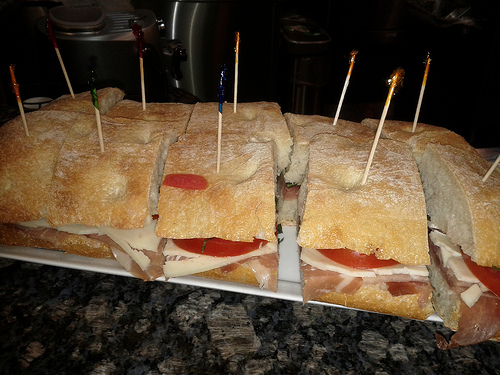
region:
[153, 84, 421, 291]
the toothpick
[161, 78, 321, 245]
the toothpick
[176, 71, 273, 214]
the toothpick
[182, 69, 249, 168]
the toothpick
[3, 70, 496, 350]
a sub sandwich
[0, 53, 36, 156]
Orange toothpick in sandwich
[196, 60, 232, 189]
blue toothpick in sandwich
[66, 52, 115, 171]
green toothpick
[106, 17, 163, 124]
red toothpick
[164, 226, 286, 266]
tomato in sandwich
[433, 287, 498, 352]
mean inside of sandwich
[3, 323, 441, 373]
Grey counter top.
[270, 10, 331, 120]
Side table in the background.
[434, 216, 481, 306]
White cheese inside of sub sandwich.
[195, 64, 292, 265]
The tooth pick is in the food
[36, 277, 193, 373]
The counter is dark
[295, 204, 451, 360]
The sandwich has tomatoes on it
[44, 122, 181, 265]
The bread is brown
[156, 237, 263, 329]
The sandwich has cheese on i t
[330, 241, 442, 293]
The tomatoes are red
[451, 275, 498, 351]
The sandwich has meat on it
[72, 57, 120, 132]
The top of the tooth pick is green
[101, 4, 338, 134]
The background is dark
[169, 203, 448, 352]
The sandwich is cut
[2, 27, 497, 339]
a large sandwich cut into smaller sandwiches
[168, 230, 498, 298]
pieces of tomato in the sandwhich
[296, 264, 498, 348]
bacon on the sandwhich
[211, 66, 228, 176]
a blue toothpick in the sandwhich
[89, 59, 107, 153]
a green toothpick in the sandwhich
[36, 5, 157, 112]
two red toothpicks in the sandwhich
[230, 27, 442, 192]
four orange toothpicks in the sandwhich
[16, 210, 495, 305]
cheese on the sandwhich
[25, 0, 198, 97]
a drink dispenser in the background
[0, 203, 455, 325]
white serving plate holding sandwhich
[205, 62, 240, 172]
toothpick with blue cellophane wrap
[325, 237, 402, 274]
tomato slice in sandwich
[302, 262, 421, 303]
prosciutto in sandwich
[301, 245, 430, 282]
slice of mozzarella cheese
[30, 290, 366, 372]
black marble counter top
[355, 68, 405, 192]
toothpick with orange cellophane wrap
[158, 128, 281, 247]
slice of Italian bread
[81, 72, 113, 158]
toothpick with green cellophane wrap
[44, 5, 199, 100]
stainless steel meat slicer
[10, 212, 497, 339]
white serving tray